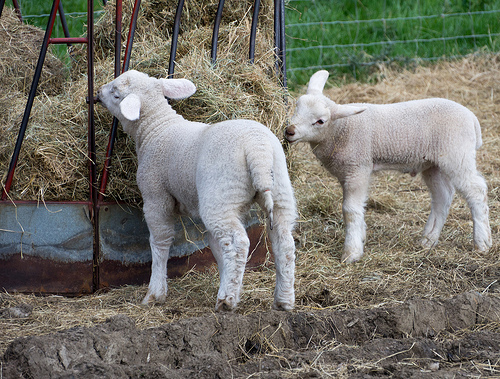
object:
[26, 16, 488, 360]
outside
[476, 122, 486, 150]
tail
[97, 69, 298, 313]
baby lamb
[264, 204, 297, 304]
leg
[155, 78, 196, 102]
lamb ear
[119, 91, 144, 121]
lamb ear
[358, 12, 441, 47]
grass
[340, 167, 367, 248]
leg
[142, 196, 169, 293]
leg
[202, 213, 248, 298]
leg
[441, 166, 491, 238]
leg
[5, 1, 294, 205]
hay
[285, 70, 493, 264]
lamb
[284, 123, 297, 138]
nose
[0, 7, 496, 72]
fence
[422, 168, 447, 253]
leg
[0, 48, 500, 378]
hay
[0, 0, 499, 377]
ground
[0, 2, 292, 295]
feeder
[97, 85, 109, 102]
nose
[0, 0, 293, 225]
food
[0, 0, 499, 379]
picture